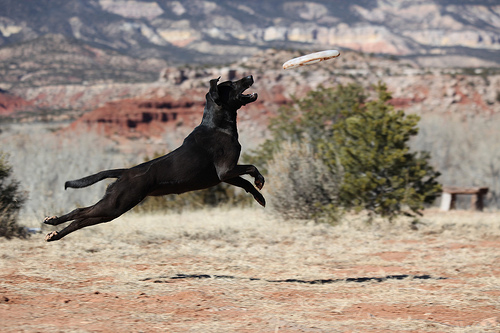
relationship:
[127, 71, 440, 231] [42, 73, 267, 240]
shrubbery behind dog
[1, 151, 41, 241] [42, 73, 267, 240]
shrubbery behind dog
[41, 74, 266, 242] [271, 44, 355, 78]
dog catch frisbee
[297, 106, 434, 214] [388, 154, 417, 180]
tree has leaves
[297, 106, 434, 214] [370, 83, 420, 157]
tree has branches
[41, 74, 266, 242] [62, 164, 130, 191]
dog has tail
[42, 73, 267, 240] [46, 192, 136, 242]
dog has leg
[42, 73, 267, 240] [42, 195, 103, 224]
dog has leg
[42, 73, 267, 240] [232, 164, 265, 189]
dog has leg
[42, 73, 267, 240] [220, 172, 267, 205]
dog has leg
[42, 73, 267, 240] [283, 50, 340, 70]
dog catch frisbee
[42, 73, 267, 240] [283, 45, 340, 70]
dog catch frisbee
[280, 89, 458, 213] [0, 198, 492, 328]
grass on ground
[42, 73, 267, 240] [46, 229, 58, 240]
dog has paw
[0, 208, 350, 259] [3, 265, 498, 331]
grass on dirt